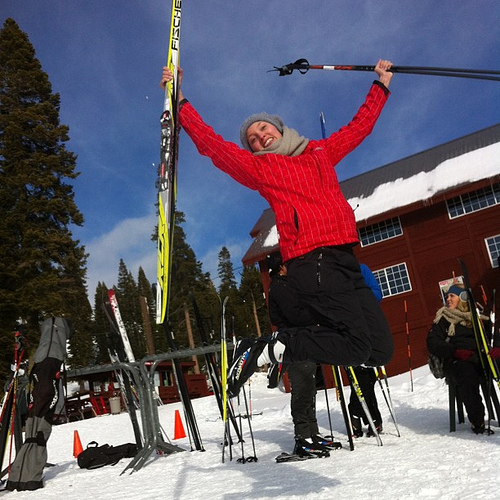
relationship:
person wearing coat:
[160, 60, 396, 396] [170, 77, 390, 260]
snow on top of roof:
[263, 136, 499, 249] [234, 117, 489, 246]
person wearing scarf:
[160, 60, 396, 396] [433, 302, 468, 333]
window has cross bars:
[371, 263, 416, 295] [367, 261, 411, 299]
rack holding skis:
[49, 329, 264, 479] [214, 294, 234, 461]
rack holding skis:
[49, 329, 264, 479] [106, 290, 150, 458]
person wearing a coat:
[160, 60, 396, 371] [176, 79, 390, 262]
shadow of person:
[175, 451, 339, 497] [160, 60, 396, 371]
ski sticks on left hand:
[265, 57, 498, 92] [372, 54, 397, 89]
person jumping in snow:
[160, 60, 396, 396] [0, 368, 498, 498]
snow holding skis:
[0, 368, 498, 498] [153, 0, 187, 326]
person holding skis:
[160, 60, 396, 396] [151, 0, 181, 330]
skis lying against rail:
[4, 322, 61, 494] [61, 340, 268, 382]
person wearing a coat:
[160, 60, 396, 396] [176, 79, 390, 262]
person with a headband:
[160, 60, 396, 396] [443, 274, 469, 300]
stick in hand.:
[246, 22, 461, 98] [132, 72, 259, 184]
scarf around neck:
[261, 113, 305, 165] [221, 118, 321, 173]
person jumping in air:
[160, 60, 396, 396] [122, 38, 447, 352]